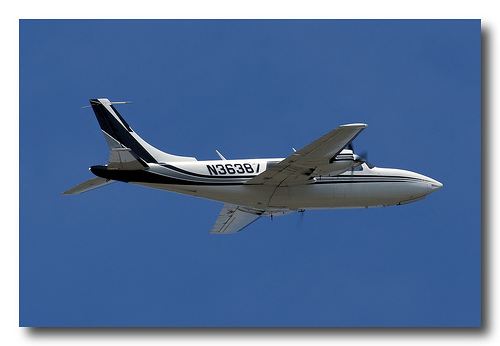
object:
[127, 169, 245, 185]
stripe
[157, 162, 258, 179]
stripe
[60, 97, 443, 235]
plane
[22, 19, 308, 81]
clouds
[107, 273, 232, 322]
clouds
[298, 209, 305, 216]
engine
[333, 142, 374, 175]
engine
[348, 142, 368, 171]
propeller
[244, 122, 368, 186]
wing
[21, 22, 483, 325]
sky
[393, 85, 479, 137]
clouds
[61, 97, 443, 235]
small plane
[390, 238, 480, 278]
clouds sky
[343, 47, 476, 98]
clouds sky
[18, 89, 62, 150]
clouds sky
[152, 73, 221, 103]
clouds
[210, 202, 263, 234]
wing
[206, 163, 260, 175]
number